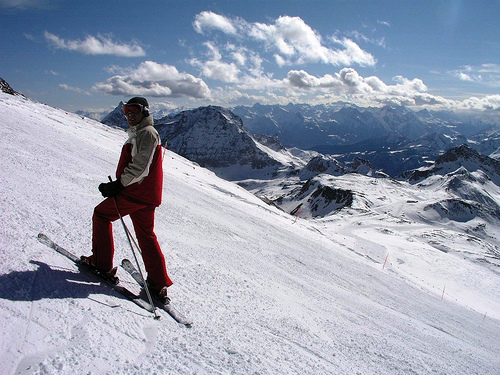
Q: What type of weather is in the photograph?
A: It is cloudy.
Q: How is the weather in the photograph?
A: It is cloudy.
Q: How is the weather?
A: It is cloudy.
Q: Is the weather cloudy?
A: Yes, it is cloudy.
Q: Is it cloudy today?
A: Yes, it is cloudy.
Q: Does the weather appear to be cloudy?
A: Yes, it is cloudy.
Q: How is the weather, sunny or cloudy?
A: It is cloudy.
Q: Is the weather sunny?
A: No, it is cloudy.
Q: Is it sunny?
A: No, it is cloudy.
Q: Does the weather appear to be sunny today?
A: No, it is cloudy.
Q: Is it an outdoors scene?
A: Yes, it is outdoors.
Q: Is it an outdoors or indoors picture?
A: It is outdoors.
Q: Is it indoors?
A: No, it is outdoors.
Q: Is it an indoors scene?
A: No, it is outdoors.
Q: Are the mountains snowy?
A: Yes, the mountains are snowy.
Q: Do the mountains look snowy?
A: Yes, the mountains are snowy.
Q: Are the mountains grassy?
A: No, the mountains are snowy.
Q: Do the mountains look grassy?
A: No, the mountains are snowy.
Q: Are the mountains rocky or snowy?
A: The mountains are snowy.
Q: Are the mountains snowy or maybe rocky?
A: The mountains are snowy.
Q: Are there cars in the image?
A: No, there are no cars.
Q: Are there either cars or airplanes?
A: No, there are no cars or airplanes.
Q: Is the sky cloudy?
A: Yes, the sky is cloudy.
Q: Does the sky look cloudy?
A: Yes, the sky is cloudy.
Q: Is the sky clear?
A: No, the sky is cloudy.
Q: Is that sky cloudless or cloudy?
A: The sky is cloudy.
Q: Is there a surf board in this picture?
A: No, there are no surfboards.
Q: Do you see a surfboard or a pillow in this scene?
A: No, there are no surfboards or pillows.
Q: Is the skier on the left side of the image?
A: Yes, the skier is on the left of the image.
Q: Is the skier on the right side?
A: No, the skier is on the left of the image.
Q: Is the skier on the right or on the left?
A: The skier is on the left of the image.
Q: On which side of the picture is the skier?
A: The skier is on the left of the image.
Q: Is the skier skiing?
A: Yes, the skier is skiing.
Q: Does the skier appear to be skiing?
A: Yes, the skier is skiing.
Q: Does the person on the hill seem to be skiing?
A: Yes, the skier is skiing.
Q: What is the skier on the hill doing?
A: The skier is skiing.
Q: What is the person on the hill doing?
A: The skier is skiing.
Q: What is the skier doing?
A: The skier is skiing.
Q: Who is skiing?
A: The skier is skiing.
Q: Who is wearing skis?
A: The skier is wearing skis.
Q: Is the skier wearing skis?
A: Yes, the skier is wearing skis.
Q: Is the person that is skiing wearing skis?
A: Yes, the skier is wearing skis.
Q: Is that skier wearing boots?
A: No, the skier is wearing skis.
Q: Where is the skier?
A: The skier is on the hill.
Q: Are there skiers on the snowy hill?
A: Yes, there is a skier on the hill.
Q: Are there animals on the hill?
A: No, there is a skier on the hill.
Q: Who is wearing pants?
A: The skier is wearing pants.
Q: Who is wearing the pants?
A: The skier is wearing pants.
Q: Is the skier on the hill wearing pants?
A: Yes, the skier is wearing pants.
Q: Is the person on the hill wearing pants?
A: Yes, the skier is wearing pants.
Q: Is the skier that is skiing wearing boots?
A: No, the skier is wearing pants.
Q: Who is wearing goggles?
A: The skier is wearing goggles.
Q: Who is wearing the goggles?
A: The skier is wearing goggles.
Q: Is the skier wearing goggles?
A: Yes, the skier is wearing goggles.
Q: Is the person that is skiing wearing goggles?
A: Yes, the skier is wearing goggles.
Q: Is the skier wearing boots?
A: No, the skier is wearing goggles.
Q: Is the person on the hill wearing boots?
A: No, the skier is wearing goggles.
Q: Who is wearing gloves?
A: The skier is wearing gloves.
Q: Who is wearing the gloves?
A: The skier is wearing gloves.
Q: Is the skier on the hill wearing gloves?
A: Yes, the skier is wearing gloves.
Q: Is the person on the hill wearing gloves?
A: Yes, the skier is wearing gloves.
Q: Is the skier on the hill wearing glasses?
A: No, the skier is wearing gloves.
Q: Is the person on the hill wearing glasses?
A: No, the skier is wearing gloves.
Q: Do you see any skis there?
A: Yes, there are skis.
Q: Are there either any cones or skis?
A: Yes, there are skis.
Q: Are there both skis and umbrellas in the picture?
A: No, there are skis but no umbrellas.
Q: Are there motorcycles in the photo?
A: No, there are no motorcycles.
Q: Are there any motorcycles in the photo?
A: No, there are no motorcycles.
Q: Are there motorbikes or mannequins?
A: No, there are no motorbikes or mannequins.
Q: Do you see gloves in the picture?
A: Yes, there are gloves.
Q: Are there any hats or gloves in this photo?
A: Yes, there are gloves.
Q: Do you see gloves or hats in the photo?
A: Yes, there are gloves.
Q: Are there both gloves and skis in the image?
A: Yes, there are both gloves and skis.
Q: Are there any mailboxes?
A: No, there are no mailboxes.